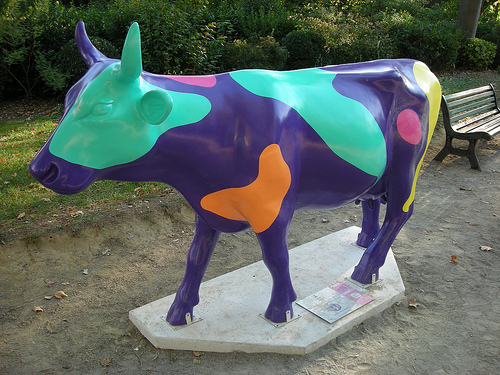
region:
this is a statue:
[28, 17, 440, 327]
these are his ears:
[70, 17, 146, 77]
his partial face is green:
[49, 21, 211, 168]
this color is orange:
[199, 140, 293, 238]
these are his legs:
[353, 189, 420, 287]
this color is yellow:
[402, 58, 444, 228]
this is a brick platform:
[122, 219, 407, 359]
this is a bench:
[433, 79, 497, 168]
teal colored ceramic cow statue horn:
[117, 16, 146, 86]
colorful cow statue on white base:
[27, 7, 441, 360]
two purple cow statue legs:
[150, 225, 302, 332]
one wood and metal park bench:
[441, 70, 499, 165]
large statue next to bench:
[23, 16, 498, 333]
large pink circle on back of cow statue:
[391, 99, 426, 152]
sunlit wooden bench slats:
[441, 77, 499, 174]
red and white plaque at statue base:
[294, 275, 383, 327]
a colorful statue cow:
[33, 14, 445, 327]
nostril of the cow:
[32, 163, 64, 184]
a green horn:
[107, 29, 147, 74]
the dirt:
[76, 322, 116, 372]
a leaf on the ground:
[48, 287, 68, 306]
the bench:
[446, 91, 498, 138]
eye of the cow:
[75, 99, 119, 120]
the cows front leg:
[265, 249, 300, 319]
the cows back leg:
[350, 228, 401, 280]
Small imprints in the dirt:
[8, 322, 56, 362]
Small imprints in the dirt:
[8, 266, 74, 301]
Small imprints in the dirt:
[60, 241, 123, 287]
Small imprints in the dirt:
[117, 219, 154, 259]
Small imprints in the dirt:
[73, 322, 124, 362]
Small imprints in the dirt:
[168, 350, 188, 365]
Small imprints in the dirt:
[321, 347, 392, 372]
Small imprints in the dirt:
[370, 315, 421, 366]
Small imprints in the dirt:
[411, 302, 459, 358]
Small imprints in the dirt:
[408, 251, 472, 301]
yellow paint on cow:
[416, 66, 436, 94]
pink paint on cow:
[403, 116, 420, 140]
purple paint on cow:
[203, 137, 225, 154]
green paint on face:
[87, 138, 110, 155]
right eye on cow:
[84, 98, 121, 124]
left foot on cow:
[152, 294, 202, 331]